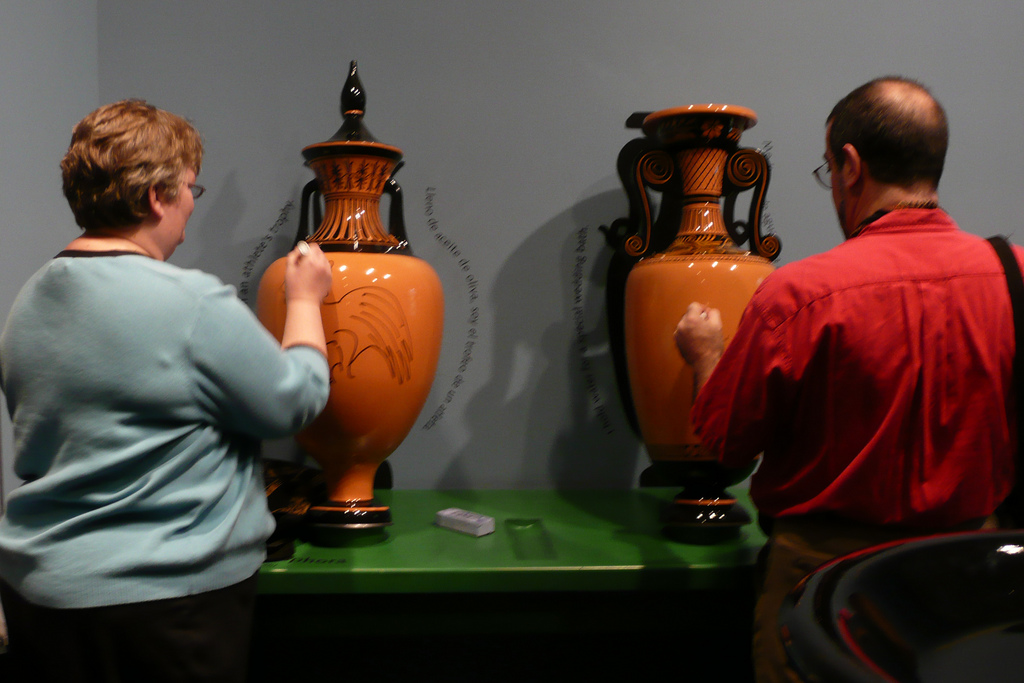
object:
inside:
[0, 0, 1024, 683]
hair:
[60, 98, 205, 233]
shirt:
[0, 249, 330, 612]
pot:
[596, 101, 785, 543]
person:
[0, 98, 347, 683]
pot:
[244, 52, 453, 546]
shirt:
[680, 201, 1024, 551]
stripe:
[308, 189, 347, 246]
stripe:
[355, 157, 372, 192]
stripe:
[327, 157, 347, 191]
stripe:
[337, 198, 361, 240]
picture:
[3, 0, 1024, 683]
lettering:
[421, 188, 484, 434]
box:
[431, 504, 497, 537]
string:
[860, 204, 963, 234]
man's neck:
[838, 184, 963, 237]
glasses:
[177, 180, 205, 199]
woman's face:
[154, 152, 207, 248]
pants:
[8, 575, 259, 683]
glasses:
[809, 150, 855, 192]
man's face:
[823, 114, 847, 237]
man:
[669, 73, 1024, 683]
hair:
[821, 72, 949, 193]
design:
[318, 283, 413, 388]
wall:
[0, 0, 1024, 491]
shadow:
[433, 182, 680, 539]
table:
[232, 486, 805, 599]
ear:
[147, 167, 171, 219]